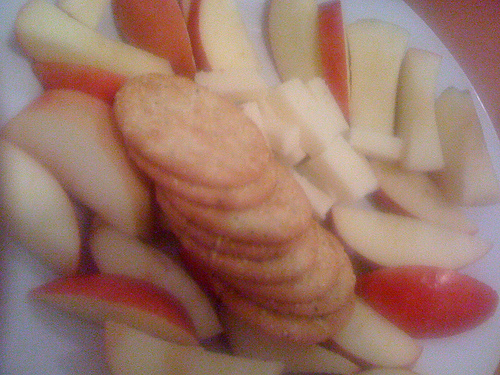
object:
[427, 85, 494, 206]
apple slice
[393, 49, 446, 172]
apple slice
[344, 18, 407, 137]
apple slice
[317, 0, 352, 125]
apple slice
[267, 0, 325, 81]
apple slice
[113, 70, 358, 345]
crackers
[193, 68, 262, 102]
cheese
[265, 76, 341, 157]
cheese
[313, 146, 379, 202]
cheese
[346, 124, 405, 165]
cheese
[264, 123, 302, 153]
cheese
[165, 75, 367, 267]
outdoors scene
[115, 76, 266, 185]
cracker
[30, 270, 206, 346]
apple slice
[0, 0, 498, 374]
food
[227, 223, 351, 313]
cracker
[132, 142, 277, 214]
cracker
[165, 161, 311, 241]
cracker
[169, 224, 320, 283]
cracker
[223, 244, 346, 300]
cracker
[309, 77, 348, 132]
cheese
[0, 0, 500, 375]
background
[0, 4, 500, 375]
plate